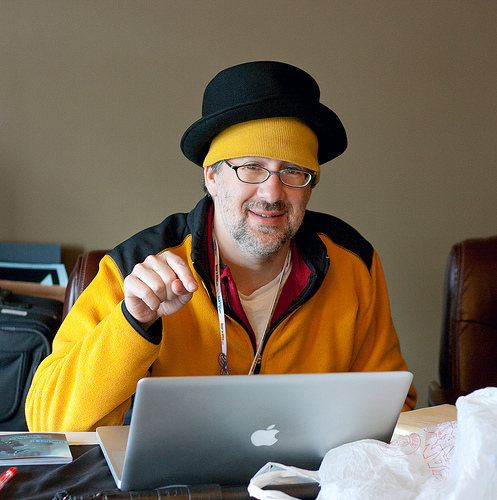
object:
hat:
[178, 61, 349, 166]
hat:
[202, 117, 321, 186]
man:
[22, 61, 417, 433]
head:
[203, 116, 320, 269]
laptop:
[94, 370, 415, 491]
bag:
[1, 288, 62, 432]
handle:
[0, 290, 31, 319]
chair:
[428, 235, 496, 406]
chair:
[61, 248, 112, 323]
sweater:
[25, 194, 417, 432]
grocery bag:
[247, 387, 497, 499]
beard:
[218, 183, 309, 261]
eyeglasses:
[224, 159, 317, 188]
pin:
[216, 351, 230, 375]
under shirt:
[238, 251, 291, 350]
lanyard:
[211, 228, 293, 375]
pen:
[1, 467, 20, 490]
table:
[1, 402, 456, 499]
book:
[0, 432, 73, 467]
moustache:
[244, 200, 291, 212]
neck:
[214, 207, 291, 276]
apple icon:
[249, 423, 286, 451]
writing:
[379, 419, 458, 482]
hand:
[122, 251, 198, 324]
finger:
[164, 251, 200, 293]